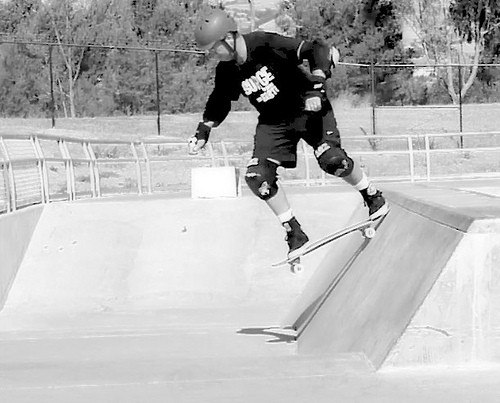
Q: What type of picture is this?
A: Black and White.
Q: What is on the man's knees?
A: Knee pads.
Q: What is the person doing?
A: Skateboarding.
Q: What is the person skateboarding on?
A: Ramp.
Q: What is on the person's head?
A: Helmet.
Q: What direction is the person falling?
A: Down.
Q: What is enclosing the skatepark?
A: Tall chain link fence.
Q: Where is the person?
A: Skatepark.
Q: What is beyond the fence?
A: Grass and trees.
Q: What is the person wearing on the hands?
A: Skate gloves.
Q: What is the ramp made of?
A: Stone.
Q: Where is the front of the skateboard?
A: The air.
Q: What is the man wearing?
A: Helmet.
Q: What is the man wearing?
A: Elbow pads.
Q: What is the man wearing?
A: Knee pads.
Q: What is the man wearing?
A: Sneakers.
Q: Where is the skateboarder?
A: A ramp.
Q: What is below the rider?
A: A shadow on the ground.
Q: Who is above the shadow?
A: A man on a skateboard.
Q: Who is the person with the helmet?
A: Skateboarder on a ramp.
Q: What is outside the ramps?
A: Fence surrounding skateboard park.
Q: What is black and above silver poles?
A: Chain link fence by grass.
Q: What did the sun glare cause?
A: Shadow on ground of ramp.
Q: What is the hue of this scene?
A: A black and white photo.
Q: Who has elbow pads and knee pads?
A: Man on a skateboard.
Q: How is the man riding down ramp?
A: Feet on skate board.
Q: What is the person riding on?
A: A skateboard.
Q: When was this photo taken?
A: During the daytime.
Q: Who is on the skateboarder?
A: A guy.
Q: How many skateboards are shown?
A: One.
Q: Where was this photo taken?
A: At a skateboard park.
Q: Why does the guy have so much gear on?
A: For protection.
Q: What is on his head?
A: A helmet.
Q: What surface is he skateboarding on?
A: Concrete.